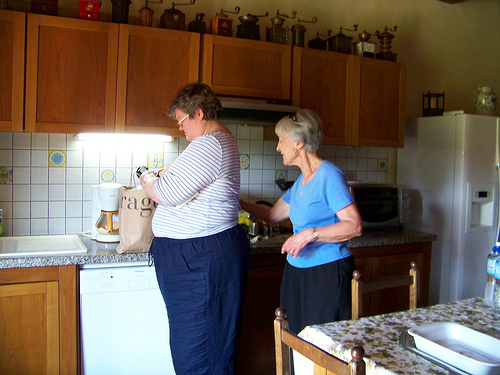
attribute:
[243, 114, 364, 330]
lady — going, looking, checking groceries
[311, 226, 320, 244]
watch — silver, gold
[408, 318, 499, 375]
dish — white, oblong, long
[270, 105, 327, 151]
woman's head — grey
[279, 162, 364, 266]
shirt — blue, light blue, short sleeved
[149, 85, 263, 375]
woman — older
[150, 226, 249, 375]
pants — blue, purple, big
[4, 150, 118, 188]
tile — white, red, blue, small, yellow, ceramic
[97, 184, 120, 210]
candle — white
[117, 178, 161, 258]
bag — paper, brown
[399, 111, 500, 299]
refrigerator — side by side, white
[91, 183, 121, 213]
coffer maker — white, small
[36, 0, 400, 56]
coffee grinders — collected, big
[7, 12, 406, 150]
cabinets — overheard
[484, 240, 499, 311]
water — bottled, zephyrhills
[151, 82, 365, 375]
friends — standing, unpacking, back from shopping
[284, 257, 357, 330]
pants — dark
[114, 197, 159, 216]
letters — black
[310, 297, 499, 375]
table — white, gold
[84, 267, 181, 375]
dishwasher — white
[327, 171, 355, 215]
sleeves — short